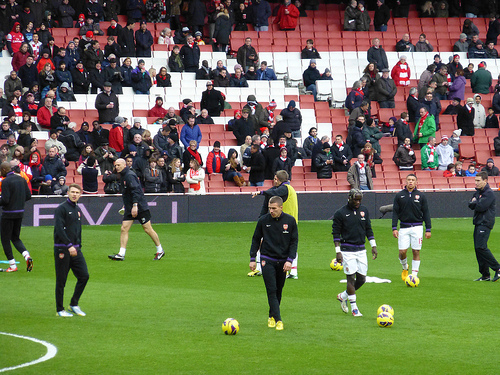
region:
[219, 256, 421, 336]
five yellow and blue soccer balls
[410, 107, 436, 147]
a man wearing a green jacket and red shirt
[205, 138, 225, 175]
a person in the fan stands wearing red and black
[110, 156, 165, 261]
a bald man wearing a jacket and shorts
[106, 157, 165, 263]
a man wearing Nike shoes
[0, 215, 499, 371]
short green grass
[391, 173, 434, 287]
a man wearing a black jacket, white shorts, and yellow shoes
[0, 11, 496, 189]
spectator seats are orange and white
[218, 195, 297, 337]
a man looking at a soccer ball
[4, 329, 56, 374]
white line in the grass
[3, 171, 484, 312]
group of players on field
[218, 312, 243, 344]
yellow and black ball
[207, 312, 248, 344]
yellow and black soccer ball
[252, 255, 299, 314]
black pants on man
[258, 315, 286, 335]
yellow shoes on feet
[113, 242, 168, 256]
white socks on ankles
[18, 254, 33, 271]
orange and black cleats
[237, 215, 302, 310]
black soccer warm ups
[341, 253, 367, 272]
white shorts on man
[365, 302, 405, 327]
two yellow soccer balls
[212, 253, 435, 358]
five soccer balls on the ground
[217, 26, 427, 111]
red and white bleacher seats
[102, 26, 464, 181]
several people sitting in the bleachers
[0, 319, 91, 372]
white line on a soccer field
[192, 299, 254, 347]
a yellow and purple soccer ball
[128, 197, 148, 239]
a man wearing black shorts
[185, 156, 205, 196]
a woman with her arms crossed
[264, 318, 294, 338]
a man wearing yellow shoes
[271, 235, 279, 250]
man wearing black jacket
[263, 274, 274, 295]
man wearing black pants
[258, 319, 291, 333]
man wearing yellow sneakers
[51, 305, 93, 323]
man wearing white sneakers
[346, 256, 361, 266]
man wearing white shorts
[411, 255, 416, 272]
man wearing white socks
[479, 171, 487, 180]
man with short hair cut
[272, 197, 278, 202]
man has is black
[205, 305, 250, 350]
yellow and black ball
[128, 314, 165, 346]
green grass in field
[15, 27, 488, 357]
players getting ready for a game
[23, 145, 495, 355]
these players are preparing for a match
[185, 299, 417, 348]
soccer balls on a field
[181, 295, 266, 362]
the soccer balls are yellow and black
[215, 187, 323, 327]
the player's colors are black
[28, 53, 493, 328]
everyone is getting ready for the match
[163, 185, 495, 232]
a stadium wall behind the players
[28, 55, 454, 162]
these fans are settling in for the game